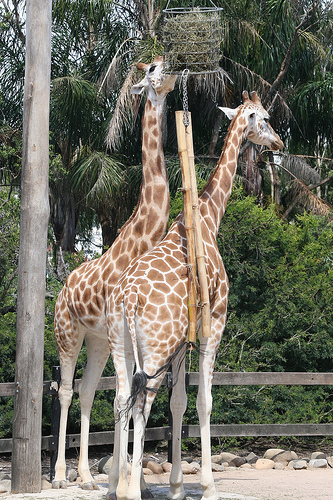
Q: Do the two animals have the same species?
A: Yes, all the animals are giraffes.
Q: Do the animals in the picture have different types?
A: No, all the animals are giraffes.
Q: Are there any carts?
A: No, there are no carts.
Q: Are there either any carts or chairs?
A: No, there are no carts or chairs.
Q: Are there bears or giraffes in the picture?
A: Yes, there is a giraffe.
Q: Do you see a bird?
A: No, there are no birds.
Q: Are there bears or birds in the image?
A: No, there are no birds or bears.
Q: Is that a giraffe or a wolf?
A: That is a giraffe.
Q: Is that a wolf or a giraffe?
A: That is a giraffe.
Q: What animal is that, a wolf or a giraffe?
A: That is a giraffe.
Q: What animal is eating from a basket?
A: The giraffe is eating from a basket.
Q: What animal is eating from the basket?
A: The giraffe is eating from a basket.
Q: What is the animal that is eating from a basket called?
A: The animal is a giraffe.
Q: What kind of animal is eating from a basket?
A: The animal is a giraffe.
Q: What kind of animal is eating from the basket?
A: The animal is a giraffe.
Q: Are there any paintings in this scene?
A: No, there are no paintings.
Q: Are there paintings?
A: No, there are no paintings.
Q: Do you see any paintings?
A: No, there are no paintings.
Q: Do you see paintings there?
A: No, there are no paintings.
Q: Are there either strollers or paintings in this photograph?
A: No, there are no paintings or strollers.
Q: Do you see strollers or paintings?
A: No, there are no paintings or strollers.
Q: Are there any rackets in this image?
A: No, there are no rackets.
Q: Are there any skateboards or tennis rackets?
A: No, there are no tennis rackets or skateboards.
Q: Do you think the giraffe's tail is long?
A: Yes, the tail is long.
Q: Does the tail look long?
A: Yes, the tail is long.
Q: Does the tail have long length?
A: Yes, the tail is long.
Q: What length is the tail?
A: The tail is long.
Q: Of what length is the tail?
A: The tail is long.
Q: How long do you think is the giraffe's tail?
A: The tail is long.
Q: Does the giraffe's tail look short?
A: No, the tail is long.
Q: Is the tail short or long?
A: The tail is long.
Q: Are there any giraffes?
A: Yes, there is a giraffe.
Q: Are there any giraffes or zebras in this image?
A: Yes, there is a giraffe.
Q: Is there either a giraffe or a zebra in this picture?
A: Yes, there is a giraffe.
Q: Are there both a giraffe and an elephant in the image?
A: No, there is a giraffe but no elephants.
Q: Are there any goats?
A: No, there are no goats.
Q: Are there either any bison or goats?
A: No, there are no goats or bison.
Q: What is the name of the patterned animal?
A: The animal is a giraffe.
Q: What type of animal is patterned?
A: The animal is a giraffe.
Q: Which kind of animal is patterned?
A: The animal is a giraffe.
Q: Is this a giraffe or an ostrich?
A: This is a giraffe.